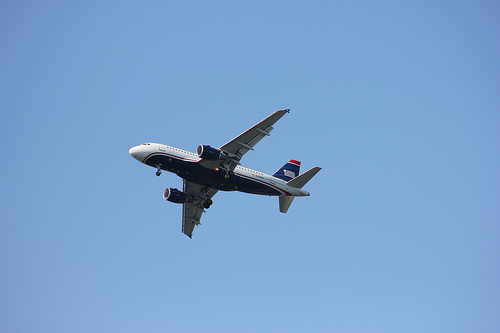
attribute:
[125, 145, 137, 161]
nose — white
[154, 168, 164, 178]
front wheel — black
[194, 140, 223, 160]
engine — white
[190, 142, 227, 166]
engine — blue and white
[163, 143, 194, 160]
windows — passenger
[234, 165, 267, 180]
windows — passenger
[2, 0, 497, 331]
clear sky — blue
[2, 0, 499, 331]
skies — blue, clear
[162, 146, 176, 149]
window — small 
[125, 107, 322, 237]
airplane — red, white, and blue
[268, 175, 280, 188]
door — white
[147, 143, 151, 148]
window — small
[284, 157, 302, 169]
stripe — red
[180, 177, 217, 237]
wing — white 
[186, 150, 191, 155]
window — small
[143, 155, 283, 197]
underside — dark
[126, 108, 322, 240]
plane — blue white and red, white, blue, red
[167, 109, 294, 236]
wings — grey, triangular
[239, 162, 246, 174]
window — small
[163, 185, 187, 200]
engine — blue, white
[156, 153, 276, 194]
stripe — red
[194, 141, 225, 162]
engine — blue, white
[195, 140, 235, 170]
engine — round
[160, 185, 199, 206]
engine — round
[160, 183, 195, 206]
engine — blue and white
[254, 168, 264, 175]
window — small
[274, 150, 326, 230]
tail end — red, white, blue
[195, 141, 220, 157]
engine — blue, white 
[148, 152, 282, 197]
underbody — blue